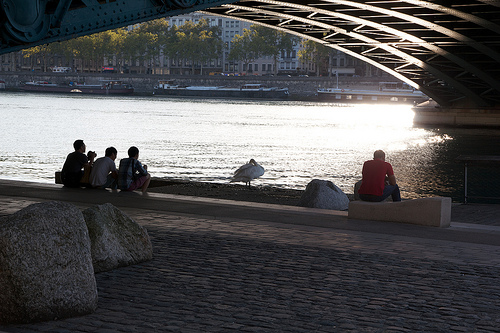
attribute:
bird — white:
[233, 154, 268, 186]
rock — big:
[77, 198, 156, 274]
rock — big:
[1, 197, 101, 320]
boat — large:
[156, 81, 291, 99]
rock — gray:
[300, 175, 350, 212]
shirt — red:
[362, 161, 390, 196]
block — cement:
[334, 192, 463, 229]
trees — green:
[82, 16, 280, 66]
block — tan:
[348, 196, 451, 226]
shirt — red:
[359, 159, 389, 200]